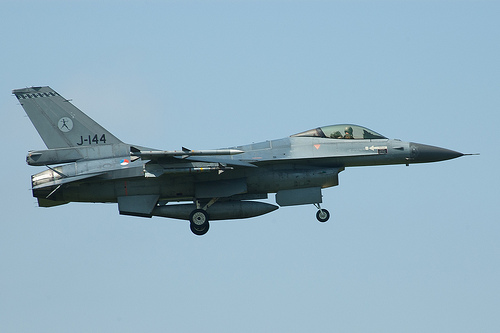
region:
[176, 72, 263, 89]
crystal clear blue skies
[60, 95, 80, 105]
small white pole on tail of plane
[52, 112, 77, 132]
small white circle on tail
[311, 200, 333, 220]
small black wheel on plane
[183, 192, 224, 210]
silver rivets holding large wheel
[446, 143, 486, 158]
point on plane's nose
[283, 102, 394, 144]
cockpit on the plane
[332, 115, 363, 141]
pilot in the seat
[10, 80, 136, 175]
silver tail on plane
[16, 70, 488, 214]
large gray jet in the sky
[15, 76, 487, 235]
A fighter jet in the air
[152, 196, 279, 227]
a bomb on the bottom of plane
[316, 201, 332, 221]
front wheel of plane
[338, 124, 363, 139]
a man on the inside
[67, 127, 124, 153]
black numbers on the back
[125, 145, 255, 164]
missils on the side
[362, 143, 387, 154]
a white arrow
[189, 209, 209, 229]
a black wheel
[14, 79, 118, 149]
a tail fin of a plane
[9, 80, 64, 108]
a design across the top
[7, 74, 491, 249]
This is an F-16 Falcon fighter jet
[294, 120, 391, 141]
The jet's canopy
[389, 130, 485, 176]
This is the jet's nose section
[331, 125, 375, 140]
The pilot is sitting in the cockpit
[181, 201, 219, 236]
The rear landing gears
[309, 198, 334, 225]
The front landing gear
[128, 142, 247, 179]
Missiles are on the wing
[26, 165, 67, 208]
The jet's engine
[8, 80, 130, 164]
The jet's tail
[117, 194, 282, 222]
This is a fuel tank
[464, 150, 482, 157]
Tip of plane has a needle nose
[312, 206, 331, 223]
Front wheel for landing is down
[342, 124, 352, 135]
Pilot is wearing a helmet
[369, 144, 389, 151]
Plane has white arrow pointing left on side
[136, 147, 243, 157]
Plane is equipped with missiles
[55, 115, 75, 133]
Plane's tail has circular white logo on it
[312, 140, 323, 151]
Upside down red triangle is on side of plane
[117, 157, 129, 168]
Red, white, and blue circle on side of plane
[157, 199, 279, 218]
Plane has large missile underneath it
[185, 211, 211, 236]
Two rear wheels are down to prepare for landing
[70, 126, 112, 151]
j-144 written on back of plane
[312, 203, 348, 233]
small front wheel on plane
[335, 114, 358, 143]
pilot in cockpit of airplane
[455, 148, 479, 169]
pointed metal devise on front of plane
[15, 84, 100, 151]
back grey wing of plane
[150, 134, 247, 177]
rocket like device on right of plane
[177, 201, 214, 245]
back two small wheels on plane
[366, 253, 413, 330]
blue patch of sky under plane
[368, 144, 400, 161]
white arrow pointing left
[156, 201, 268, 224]
large rocket type device on bottom of plane